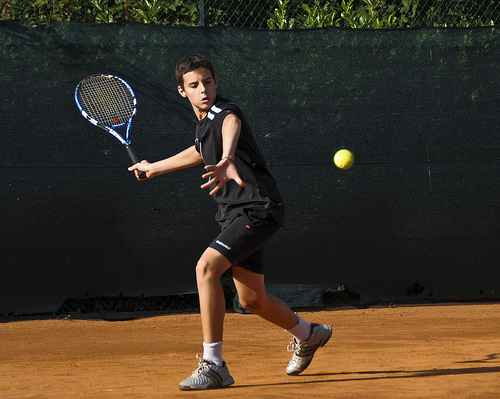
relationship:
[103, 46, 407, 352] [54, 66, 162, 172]
man with racket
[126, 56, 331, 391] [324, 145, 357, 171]
man about to hit tennis ball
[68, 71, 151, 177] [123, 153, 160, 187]
tennis racket in man's hand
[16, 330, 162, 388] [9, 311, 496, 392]
dirt ground of tennis court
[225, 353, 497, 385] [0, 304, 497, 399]
black shadow casted on dirt ground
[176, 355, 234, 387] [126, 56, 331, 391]
left sneaker of man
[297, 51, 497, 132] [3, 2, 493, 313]
green screen attached to metal fence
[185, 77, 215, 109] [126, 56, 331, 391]
face of man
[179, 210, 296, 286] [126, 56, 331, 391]
black shorts on man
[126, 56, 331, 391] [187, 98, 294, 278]
man in black outfit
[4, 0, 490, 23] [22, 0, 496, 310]
foliage behind fence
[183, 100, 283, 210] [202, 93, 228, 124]
tank top with white stripes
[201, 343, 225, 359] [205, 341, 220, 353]
white socks pulled up above ankle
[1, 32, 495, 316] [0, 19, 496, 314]
black cover on fence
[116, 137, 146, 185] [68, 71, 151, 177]
black handle on tennis racket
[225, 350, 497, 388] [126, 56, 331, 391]
black shadow of man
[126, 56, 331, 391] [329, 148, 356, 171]
man preparing to hit tennis ball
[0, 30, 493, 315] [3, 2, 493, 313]
green tarp over metal fence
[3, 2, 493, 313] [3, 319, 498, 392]
metal fence on tennis court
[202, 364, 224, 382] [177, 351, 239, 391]
logo on sneaker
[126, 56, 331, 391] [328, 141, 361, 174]
man hitting ball